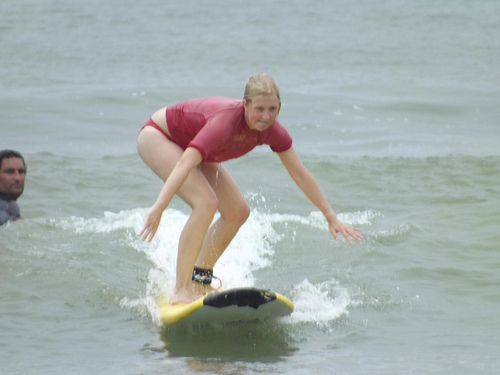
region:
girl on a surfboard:
[116, 63, 318, 355]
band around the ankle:
[189, 268, 214, 285]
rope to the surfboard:
[213, 274, 224, 290]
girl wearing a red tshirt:
[170, 95, 287, 165]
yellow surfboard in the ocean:
[134, 268, 302, 337]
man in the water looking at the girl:
[0, 140, 37, 232]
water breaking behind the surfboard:
[150, 238, 179, 288]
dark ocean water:
[334, 48, 429, 174]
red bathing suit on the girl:
[130, 108, 179, 153]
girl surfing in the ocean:
[82, 63, 342, 360]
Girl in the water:
[98, 39, 354, 362]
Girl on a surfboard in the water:
[118, 26, 333, 373]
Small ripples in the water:
[18, 321, 66, 370]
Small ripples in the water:
[72, 320, 126, 370]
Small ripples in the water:
[126, 322, 164, 374]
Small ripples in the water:
[182, 330, 225, 372]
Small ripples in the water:
[247, 319, 344, 372]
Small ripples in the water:
[295, 261, 376, 324]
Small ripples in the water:
[383, 187, 451, 262]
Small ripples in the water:
[416, 284, 459, 372]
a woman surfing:
[130, 65, 340, 341]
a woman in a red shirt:
[126, 63, 369, 290]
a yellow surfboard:
[138, 266, 305, 331]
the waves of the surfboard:
[77, 199, 354, 279]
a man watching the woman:
[2, 147, 42, 228]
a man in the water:
[0, 123, 54, 234]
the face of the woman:
[230, 75, 297, 143]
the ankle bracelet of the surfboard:
[198, 255, 223, 282]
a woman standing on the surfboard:
[122, 64, 379, 340]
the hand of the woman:
[311, 191, 382, 254]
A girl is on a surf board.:
[134, 90, 354, 367]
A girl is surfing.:
[129, 95, 343, 350]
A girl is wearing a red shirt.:
[123, 75, 304, 179]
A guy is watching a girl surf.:
[1, 151, 28, 211]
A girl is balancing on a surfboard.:
[82, 85, 322, 312]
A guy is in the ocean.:
[2, 148, 37, 229]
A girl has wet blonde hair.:
[239, 68, 307, 138]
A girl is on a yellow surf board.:
[141, 279, 326, 324]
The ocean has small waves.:
[328, 108, 455, 213]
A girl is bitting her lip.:
[204, 73, 296, 143]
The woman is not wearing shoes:
[171, 280, 211, 302]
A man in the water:
[1, 150, 28, 225]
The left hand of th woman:
[328, 213, 353, 239]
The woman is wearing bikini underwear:
[138, 119, 178, 141]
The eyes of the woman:
[254, 102, 276, 112]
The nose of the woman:
[261, 108, 272, 118]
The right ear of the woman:
[238, 91, 248, 107]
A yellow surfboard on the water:
[155, 285, 290, 325]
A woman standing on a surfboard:
[136, 74, 357, 300]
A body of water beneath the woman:
[0, 1, 497, 373]